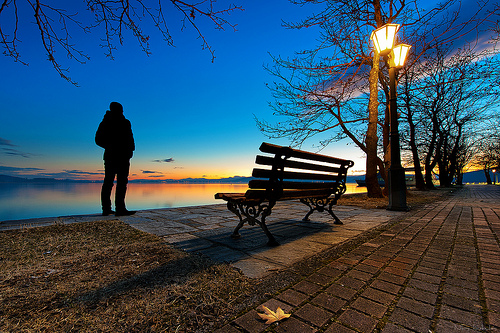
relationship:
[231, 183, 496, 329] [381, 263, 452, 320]
walkway made of bricks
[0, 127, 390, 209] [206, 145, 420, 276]
water overlooking bench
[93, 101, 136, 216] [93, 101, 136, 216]
man a man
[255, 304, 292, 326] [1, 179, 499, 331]
leaf on ground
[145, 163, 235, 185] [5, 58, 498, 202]
sunset s visible on horizon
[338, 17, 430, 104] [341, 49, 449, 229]
lamps are yellow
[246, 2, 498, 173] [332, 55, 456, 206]
trees are bare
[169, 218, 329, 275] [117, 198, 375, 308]
shadow on ground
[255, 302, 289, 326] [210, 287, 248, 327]
leaf on ground